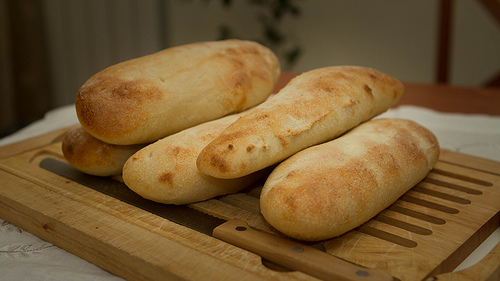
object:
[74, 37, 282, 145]
bread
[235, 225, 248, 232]
bolt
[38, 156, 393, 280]
knife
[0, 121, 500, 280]
cutting board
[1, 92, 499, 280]
table cloth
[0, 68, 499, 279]
table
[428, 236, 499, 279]
handle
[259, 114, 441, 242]
bread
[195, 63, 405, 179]
bread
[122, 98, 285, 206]
bread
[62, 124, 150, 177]
bread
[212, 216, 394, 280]
handle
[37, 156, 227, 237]
blade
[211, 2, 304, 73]
plant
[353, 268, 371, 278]
rivet